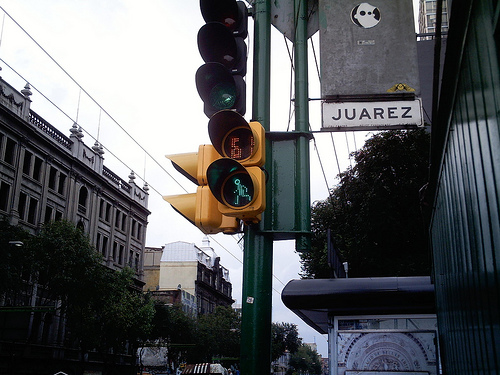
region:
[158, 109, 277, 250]
a peatonal traffic light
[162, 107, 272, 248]
peatonal traffic light is yellow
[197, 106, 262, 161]
red light of peatonal traffic light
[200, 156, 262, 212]
green light of peatonal traffic light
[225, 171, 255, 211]
a green man on peatonal traffic light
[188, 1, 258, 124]
traffic light is off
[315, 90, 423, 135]
sign with letter JUAREZ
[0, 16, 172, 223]
power lines above building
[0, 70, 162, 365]
trees in front a building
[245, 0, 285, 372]
the pole is green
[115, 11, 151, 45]
this is the sky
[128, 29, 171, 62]
the sky has clouds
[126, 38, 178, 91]
the clouds are white in color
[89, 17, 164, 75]
the sky is bright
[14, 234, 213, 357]
these are some trees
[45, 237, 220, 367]
the trees are tall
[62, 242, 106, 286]
the leaves are green in color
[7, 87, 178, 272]
these are some buildings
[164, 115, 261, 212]
these are some traffic lights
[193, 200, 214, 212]
the cover is yellow in color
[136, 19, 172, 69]
this is the sky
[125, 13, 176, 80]
the sky is bright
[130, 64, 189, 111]
the clouds are white in color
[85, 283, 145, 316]
the leaves are green in color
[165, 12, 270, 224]
these are traffic lights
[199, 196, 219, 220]
the cover is yellow in color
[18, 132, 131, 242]
this is a building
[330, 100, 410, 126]
the writings are in bold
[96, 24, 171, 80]
this is the sky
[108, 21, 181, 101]
the sky is blue in color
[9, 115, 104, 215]
this is a building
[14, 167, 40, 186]
this is the wall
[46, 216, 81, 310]
this is a tree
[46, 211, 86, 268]
the leaves are green in color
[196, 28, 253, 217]
this is a traffic light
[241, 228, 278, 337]
this is a pole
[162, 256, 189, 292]
the wall is brown in color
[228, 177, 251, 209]
Small green man running left on a light.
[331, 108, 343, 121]
J in JUAREZ.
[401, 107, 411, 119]
Black Z in JUAREZ.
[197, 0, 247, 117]
A black traffic light with green illuminated.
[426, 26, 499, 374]
The side of a shiny dark green building.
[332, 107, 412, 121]
The black word JUAREZ.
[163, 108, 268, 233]
A smaller yellow traffic light under a black one.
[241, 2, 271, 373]
A thick green metal pole with traffic lights on it.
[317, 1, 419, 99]
The back of a metal sign above JUAREZ with a black and white sticker on it.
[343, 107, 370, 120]
Large black U A in JUAREZ